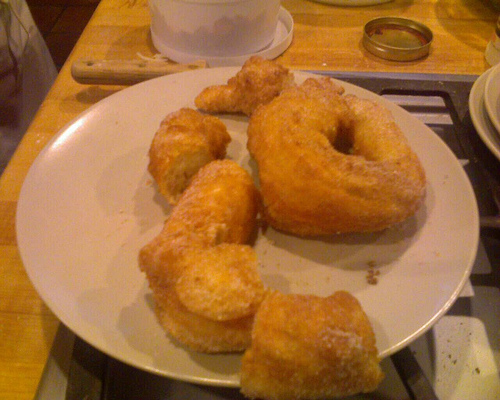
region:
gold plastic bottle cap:
[362, 18, 436, 63]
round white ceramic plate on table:
[13, 63, 479, 385]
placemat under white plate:
[33, 319, 240, 396]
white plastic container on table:
[147, 3, 295, 64]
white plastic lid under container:
[147, 6, 296, 65]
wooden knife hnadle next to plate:
[71, 54, 208, 86]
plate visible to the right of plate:
[467, 63, 498, 155]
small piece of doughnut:
[195, 54, 295, 116]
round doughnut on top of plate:
[248, 76, 425, 242]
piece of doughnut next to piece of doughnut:
[149, 106, 234, 203]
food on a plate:
[123, 86, 383, 297]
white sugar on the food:
[143, 151, 259, 316]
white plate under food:
[31, 218, 129, 308]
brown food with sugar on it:
[257, 148, 359, 238]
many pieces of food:
[126, 68, 445, 360]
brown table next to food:
[2, 295, 48, 370]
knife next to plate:
[95, 37, 240, 100]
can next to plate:
[346, 11, 448, 70]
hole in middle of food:
[291, 72, 411, 209]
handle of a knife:
[94, 31, 186, 98]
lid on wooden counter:
[362, 15, 432, 58]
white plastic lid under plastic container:
[144, 3, 295, 65]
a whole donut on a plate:
[250, 79, 425, 234]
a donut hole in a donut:
[325, 111, 378, 158]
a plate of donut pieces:
[17, 61, 477, 388]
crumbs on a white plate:
[362, 260, 384, 287]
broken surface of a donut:
[173, 241, 258, 317]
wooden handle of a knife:
[67, 56, 209, 83]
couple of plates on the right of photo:
[467, 59, 498, 156]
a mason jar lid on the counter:
[357, 10, 438, 70]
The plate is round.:
[16, 61, 488, 392]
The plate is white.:
[12, 60, 489, 391]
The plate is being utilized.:
[9, 61, 484, 394]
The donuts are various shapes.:
[139, 54, 436, 399]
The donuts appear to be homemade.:
[106, 47, 428, 399]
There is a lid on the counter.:
[354, 9, 440, 62]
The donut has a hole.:
[321, 110, 378, 167]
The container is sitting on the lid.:
[143, 2, 311, 66]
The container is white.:
[144, 0, 304, 67]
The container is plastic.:
[141, 0, 300, 68]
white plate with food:
[5, 36, 486, 399]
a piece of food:
[226, 282, 416, 399]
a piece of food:
[128, 222, 291, 352]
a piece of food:
[121, 142, 268, 295]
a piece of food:
[135, 89, 244, 209]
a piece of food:
[192, 38, 304, 125]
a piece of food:
[239, 78, 436, 238]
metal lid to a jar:
[331, 8, 440, 73]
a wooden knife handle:
[47, 41, 223, 93]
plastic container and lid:
[106, 1, 303, 63]